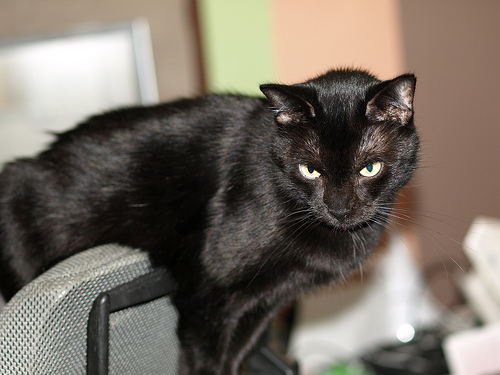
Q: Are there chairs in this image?
A: Yes, there is a chair.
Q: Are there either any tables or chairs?
A: Yes, there is a chair.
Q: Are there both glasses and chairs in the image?
A: No, there is a chair but no glasses.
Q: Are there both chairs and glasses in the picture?
A: No, there is a chair but no glasses.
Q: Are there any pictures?
A: No, there are no pictures.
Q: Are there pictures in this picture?
A: No, there are no pictures.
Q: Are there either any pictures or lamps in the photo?
A: No, there are no pictures or lamps.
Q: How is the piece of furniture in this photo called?
A: The piece of furniture is a chair.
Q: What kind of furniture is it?
A: The piece of furniture is a chair.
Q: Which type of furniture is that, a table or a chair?
A: That is a chair.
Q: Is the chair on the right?
A: No, the chair is on the left of the image.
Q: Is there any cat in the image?
A: Yes, there is a cat.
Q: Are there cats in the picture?
A: Yes, there is a cat.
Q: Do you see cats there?
A: Yes, there is a cat.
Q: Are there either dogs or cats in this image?
A: Yes, there is a cat.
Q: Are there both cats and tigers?
A: No, there is a cat but no tigers.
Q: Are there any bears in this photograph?
A: No, there are no bears.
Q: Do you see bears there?
A: No, there are no bears.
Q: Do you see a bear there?
A: No, there are no bears.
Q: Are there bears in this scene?
A: No, there are no bears.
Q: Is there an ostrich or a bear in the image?
A: No, there are no bears or ostriches.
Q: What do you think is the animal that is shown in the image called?
A: The animal is a cat.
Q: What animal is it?
A: The animal is a cat.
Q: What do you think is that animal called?
A: This is a cat.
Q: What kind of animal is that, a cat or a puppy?
A: This is a cat.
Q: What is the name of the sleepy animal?
A: The animal is a cat.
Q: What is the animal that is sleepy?
A: The animal is a cat.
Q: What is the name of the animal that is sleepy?
A: The animal is a cat.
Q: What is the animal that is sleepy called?
A: The animal is a cat.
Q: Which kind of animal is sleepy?
A: The animal is a cat.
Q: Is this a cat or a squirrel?
A: This is a cat.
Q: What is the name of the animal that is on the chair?
A: The animal is a cat.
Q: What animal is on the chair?
A: The animal is a cat.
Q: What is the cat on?
A: The cat is on the chair.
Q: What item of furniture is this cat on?
A: The cat is on the chair.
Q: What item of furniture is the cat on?
A: The cat is on the chair.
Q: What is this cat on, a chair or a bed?
A: The cat is on a chair.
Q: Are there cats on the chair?
A: Yes, there is a cat on the chair.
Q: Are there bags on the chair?
A: No, there is a cat on the chair.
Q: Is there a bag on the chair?
A: No, there is a cat on the chair.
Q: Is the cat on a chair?
A: Yes, the cat is on a chair.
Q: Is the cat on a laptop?
A: No, the cat is on a chair.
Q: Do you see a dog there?
A: No, there are no dogs.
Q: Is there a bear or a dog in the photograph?
A: No, there are no dogs or bears.